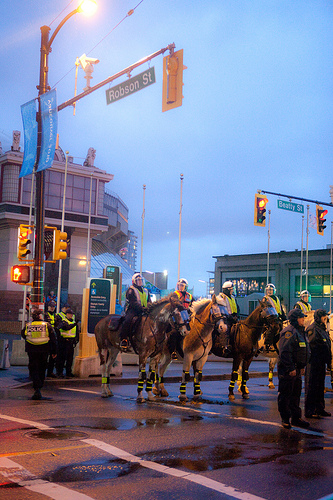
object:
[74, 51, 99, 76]
camera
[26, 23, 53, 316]
pole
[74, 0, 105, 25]
light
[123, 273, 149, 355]
policeman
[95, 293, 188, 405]
horse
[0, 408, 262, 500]
line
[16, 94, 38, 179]
banner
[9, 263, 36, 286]
pedestrian sign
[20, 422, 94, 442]
manhole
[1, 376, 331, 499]
street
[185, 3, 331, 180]
sky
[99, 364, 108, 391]
sock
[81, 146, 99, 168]
gargoyle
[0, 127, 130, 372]
building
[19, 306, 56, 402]
cop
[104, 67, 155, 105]
sign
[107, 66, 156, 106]
lettering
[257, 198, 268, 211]
trafficlight